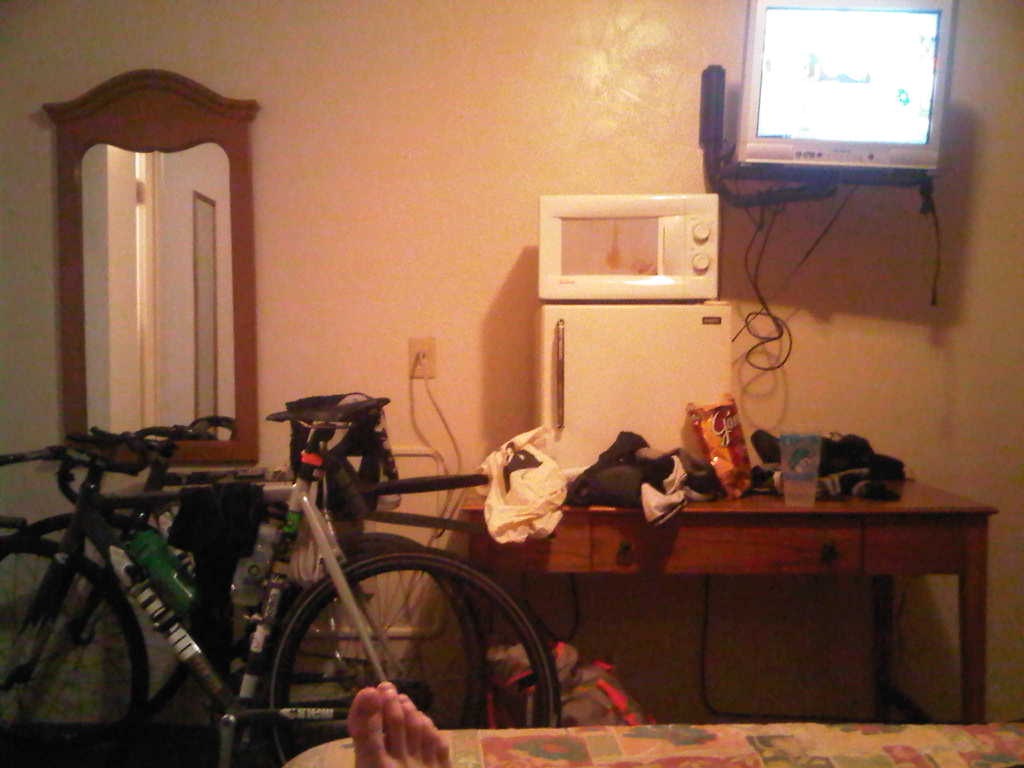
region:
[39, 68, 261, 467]
A brown framed mirror.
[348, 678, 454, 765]
A right foot and toes.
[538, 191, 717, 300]
A white microwave with two knobs.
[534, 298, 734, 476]
A white mini fridge with silver handle.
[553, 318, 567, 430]
A long dark handle of a fridge.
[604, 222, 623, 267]
Brown stain coming down a white microwave.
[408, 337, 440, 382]
Cream colored wall outlet.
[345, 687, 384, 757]
A big toe on a right foot.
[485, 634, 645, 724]
A grey and pink backpack.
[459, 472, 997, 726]
A long brown desk with drawer.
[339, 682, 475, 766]
Toes on a man's foot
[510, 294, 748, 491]
Small white refrigerator with silver handle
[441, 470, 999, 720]
Brown wood table with one drawer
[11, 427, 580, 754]
White and black bicycle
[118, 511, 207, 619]
Green and black water bottle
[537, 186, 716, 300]
the microwave is white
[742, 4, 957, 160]
the screen is on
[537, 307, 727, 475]
the fridge is white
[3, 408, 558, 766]
the bike is indoors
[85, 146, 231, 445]
the mirror has reflection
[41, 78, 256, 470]
the frame is made of wood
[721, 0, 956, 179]
the tv is silver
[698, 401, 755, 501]
the chips are on the table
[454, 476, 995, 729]
the desk is made of wood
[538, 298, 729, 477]
A small white cube refrigerator.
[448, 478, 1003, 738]
a brown wooden table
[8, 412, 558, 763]
two bicycles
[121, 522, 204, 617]
A green water bottle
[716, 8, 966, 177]
A grey framed television mounted in the corner of the room on the wall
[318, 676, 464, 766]
A person's foot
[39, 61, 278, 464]
A long wooden framed mirror hanging on the wall.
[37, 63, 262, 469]
a mirror with a wooden frame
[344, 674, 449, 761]
the end of a person's foot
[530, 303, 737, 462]
a small white refrigerator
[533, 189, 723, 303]
a small white microwave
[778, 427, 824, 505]
a clear plastic cup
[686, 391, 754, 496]
a red, orange, and white chip bag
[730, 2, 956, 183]
an illuminated TV with a silver housing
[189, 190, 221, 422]
the reflection of a mirror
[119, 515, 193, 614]
a green water bottle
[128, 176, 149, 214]
a door hinge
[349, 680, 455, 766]
a person's barefoot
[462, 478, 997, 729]
a long brown table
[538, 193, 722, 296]
a small white microwave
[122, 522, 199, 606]
a green water bottle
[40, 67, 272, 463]
a long brown mirror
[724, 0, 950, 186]
a small gray t.v.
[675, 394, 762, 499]
a bag of chips